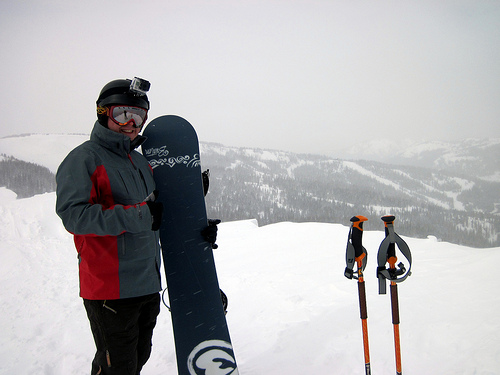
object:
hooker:
[343, 214, 371, 374]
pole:
[344, 215, 371, 374]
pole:
[377, 214, 412, 374]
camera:
[130, 76, 152, 96]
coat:
[54, 120, 161, 300]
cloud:
[265, 68, 329, 87]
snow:
[272, 235, 337, 288]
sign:
[143, 145, 201, 169]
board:
[139, 114, 238, 374]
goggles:
[107, 105, 148, 128]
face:
[108, 118, 141, 141]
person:
[54, 76, 220, 373]